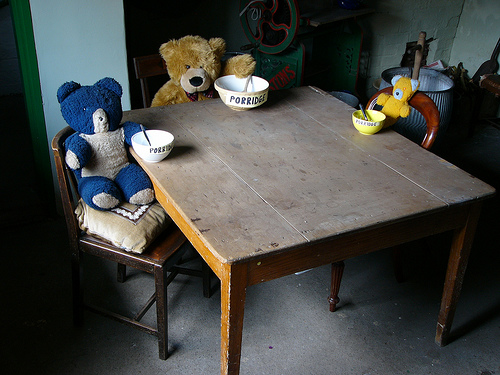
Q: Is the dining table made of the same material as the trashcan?
A: No, the dining table is made of wood and the trashcan is made of metal.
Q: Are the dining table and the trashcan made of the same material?
A: No, the dining table is made of wood and the trashcan is made of metal.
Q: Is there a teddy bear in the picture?
A: Yes, there is a teddy bear.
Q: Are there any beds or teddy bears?
A: Yes, there is a teddy bear.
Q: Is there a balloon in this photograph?
A: No, there are no balloons.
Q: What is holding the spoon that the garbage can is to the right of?
A: The teddy bear is holding the spoon.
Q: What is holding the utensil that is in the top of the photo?
A: The teddy bear is holding the spoon.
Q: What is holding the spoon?
A: The teddy bear is holding the spoon.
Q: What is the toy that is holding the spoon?
A: The toy is a teddy bear.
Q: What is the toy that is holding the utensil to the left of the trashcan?
A: The toy is a teddy bear.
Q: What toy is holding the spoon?
A: The toy is a teddy bear.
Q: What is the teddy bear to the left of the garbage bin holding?
A: The teddy bear is holding the spoon.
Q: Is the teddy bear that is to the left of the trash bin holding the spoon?
A: Yes, the teddy bear is holding the spoon.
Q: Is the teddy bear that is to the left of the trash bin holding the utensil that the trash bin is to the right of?
A: Yes, the teddy bear is holding the spoon.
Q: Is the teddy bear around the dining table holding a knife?
A: No, the teddy bear is holding the spoon.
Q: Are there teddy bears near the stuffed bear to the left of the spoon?
A: Yes, there is a teddy bear near the stuffed bear.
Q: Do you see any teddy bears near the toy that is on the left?
A: Yes, there is a teddy bear near the stuffed bear.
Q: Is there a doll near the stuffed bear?
A: No, there is a teddy bear near the stuffed bear.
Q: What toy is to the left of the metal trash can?
A: The toy is a teddy bear.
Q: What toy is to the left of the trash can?
A: The toy is a teddy bear.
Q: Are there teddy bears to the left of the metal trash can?
A: Yes, there is a teddy bear to the left of the trash bin.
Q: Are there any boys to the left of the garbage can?
A: No, there is a teddy bear to the left of the garbage can.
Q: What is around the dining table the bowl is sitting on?
A: The teddy bear is around the dining table.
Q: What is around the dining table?
A: The teddy bear is around the dining table.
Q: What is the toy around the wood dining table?
A: The toy is a teddy bear.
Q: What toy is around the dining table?
A: The toy is a teddy bear.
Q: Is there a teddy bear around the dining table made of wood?
A: Yes, there is a teddy bear around the dining table.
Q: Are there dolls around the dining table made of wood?
A: No, there is a teddy bear around the dining table.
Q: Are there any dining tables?
A: Yes, there is a dining table.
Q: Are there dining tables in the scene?
A: Yes, there is a dining table.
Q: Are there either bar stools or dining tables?
A: Yes, there is a dining table.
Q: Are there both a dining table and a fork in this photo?
A: No, there is a dining table but no forks.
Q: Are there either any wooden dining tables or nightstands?
A: Yes, there is a wood dining table.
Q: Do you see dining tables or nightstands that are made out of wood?
A: Yes, the dining table is made of wood.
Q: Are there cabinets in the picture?
A: No, there are no cabinets.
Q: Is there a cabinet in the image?
A: No, there are no cabinets.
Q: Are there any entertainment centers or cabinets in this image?
A: No, there are no cabinets or entertainment centers.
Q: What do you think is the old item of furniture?
A: The piece of furniture is a dining table.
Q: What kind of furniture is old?
A: The furniture is a dining table.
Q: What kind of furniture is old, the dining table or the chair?
A: The dining table is old.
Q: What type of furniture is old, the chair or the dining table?
A: The dining table is old.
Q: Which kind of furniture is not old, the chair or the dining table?
A: The chair is not old.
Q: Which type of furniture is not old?
A: The furniture is a chair.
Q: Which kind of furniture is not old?
A: The furniture is a chair.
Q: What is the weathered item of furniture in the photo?
A: The piece of furniture is a dining table.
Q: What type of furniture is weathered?
A: The furniture is a dining table.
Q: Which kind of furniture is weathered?
A: The furniture is a dining table.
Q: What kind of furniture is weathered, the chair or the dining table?
A: The dining table is weathered.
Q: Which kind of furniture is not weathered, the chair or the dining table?
A: The chair is not weathered.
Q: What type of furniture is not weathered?
A: The furniture is a chair.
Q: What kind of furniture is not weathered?
A: The furniture is a chair.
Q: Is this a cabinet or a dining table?
A: This is a dining table.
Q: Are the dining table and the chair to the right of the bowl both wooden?
A: Yes, both the dining table and the chair are wooden.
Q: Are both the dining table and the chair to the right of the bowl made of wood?
A: Yes, both the dining table and the chair are made of wood.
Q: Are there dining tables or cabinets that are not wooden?
A: No, there is a dining table but it is wooden.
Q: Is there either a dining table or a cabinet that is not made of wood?
A: No, there is a dining table but it is made of wood.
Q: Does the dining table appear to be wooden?
A: Yes, the dining table is wooden.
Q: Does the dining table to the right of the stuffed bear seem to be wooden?
A: Yes, the dining table is wooden.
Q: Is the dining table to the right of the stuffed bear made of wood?
A: Yes, the dining table is made of wood.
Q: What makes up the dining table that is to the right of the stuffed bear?
A: The dining table is made of wood.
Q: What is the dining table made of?
A: The dining table is made of wood.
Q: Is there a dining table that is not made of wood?
A: No, there is a dining table but it is made of wood.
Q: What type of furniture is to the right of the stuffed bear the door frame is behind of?
A: The piece of furniture is a dining table.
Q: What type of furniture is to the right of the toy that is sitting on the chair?
A: The piece of furniture is a dining table.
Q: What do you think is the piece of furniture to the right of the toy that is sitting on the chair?
A: The piece of furniture is a dining table.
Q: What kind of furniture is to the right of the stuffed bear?
A: The piece of furniture is a dining table.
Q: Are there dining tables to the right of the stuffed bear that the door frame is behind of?
A: Yes, there is a dining table to the right of the stuffed bear.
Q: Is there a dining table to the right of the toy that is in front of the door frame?
A: Yes, there is a dining table to the right of the stuffed bear.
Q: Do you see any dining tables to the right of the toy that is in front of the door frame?
A: Yes, there is a dining table to the right of the stuffed bear.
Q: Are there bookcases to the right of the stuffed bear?
A: No, there is a dining table to the right of the stuffed bear.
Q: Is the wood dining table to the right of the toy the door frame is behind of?
A: Yes, the dining table is to the right of the stuffed bear.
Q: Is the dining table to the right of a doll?
A: No, the dining table is to the right of the stuffed bear.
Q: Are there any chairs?
A: Yes, there is a chair.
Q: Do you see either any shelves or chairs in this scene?
A: Yes, there is a chair.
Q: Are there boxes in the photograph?
A: No, there are no boxes.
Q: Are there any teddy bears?
A: Yes, there is a teddy bear.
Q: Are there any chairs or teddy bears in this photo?
A: Yes, there is a teddy bear.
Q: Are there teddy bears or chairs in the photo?
A: Yes, there is a teddy bear.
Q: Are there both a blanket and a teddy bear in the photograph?
A: No, there is a teddy bear but no blankets.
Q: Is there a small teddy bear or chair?
A: Yes, there is a small teddy bear.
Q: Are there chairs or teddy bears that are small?
A: Yes, the teddy bear is small.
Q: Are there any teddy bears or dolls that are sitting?
A: Yes, the teddy bear is sitting.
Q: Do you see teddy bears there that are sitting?
A: Yes, there is a teddy bear that is sitting.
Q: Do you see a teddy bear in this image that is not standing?
A: Yes, there is a teddy bear that is sitting .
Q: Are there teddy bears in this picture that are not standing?
A: Yes, there is a teddy bear that is sitting.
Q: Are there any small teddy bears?
A: Yes, there is a small teddy bear.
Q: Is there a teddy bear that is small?
A: Yes, there is a teddy bear that is small.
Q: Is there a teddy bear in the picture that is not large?
A: Yes, there is a small teddy bear.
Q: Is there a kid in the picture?
A: No, there are no children.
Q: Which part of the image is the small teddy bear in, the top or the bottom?
A: The teddy bear is in the top of the image.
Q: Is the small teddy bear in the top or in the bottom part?
A: The teddy bear is in the top of the image.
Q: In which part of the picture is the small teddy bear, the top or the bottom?
A: The teddy bear is in the top of the image.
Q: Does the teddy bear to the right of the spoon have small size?
A: Yes, the teddy bear is small.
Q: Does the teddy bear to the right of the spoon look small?
A: Yes, the teddy bear is small.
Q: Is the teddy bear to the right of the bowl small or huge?
A: The teddy bear is small.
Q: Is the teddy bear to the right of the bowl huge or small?
A: The teddy bear is small.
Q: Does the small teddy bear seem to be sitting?
A: Yes, the teddy bear is sitting.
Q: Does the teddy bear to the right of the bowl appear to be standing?
A: No, the teddy bear is sitting.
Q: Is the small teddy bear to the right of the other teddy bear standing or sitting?
A: The teddy bear is sitting.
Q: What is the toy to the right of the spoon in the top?
A: The toy is a teddy bear.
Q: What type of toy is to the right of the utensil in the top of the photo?
A: The toy is a teddy bear.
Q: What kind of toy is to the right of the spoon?
A: The toy is a teddy bear.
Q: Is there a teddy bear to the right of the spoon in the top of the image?
A: Yes, there is a teddy bear to the right of the spoon.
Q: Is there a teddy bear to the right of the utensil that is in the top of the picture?
A: Yes, there is a teddy bear to the right of the spoon.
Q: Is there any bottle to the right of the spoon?
A: No, there is a teddy bear to the right of the spoon.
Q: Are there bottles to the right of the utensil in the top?
A: No, there is a teddy bear to the right of the spoon.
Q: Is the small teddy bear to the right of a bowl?
A: Yes, the teddy bear is to the right of a bowl.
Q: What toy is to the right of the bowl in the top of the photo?
A: The toy is a teddy bear.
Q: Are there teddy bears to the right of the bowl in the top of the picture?
A: Yes, there is a teddy bear to the right of the bowl.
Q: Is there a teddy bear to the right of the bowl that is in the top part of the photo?
A: Yes, there is a teddy bear to the right of the bowl.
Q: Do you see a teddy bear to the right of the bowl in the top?
A: Yes, there is a teddy bear to the right of the bowl.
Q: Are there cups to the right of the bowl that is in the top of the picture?
A: No, there is a teddy bear to the right of the bowl.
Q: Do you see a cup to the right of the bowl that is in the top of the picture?
A: No, there is a teddy bear to the right of the bowl.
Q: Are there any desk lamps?
A: No, there are no desk lamps.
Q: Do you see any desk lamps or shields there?
A: No, there are no desk lamps or shields.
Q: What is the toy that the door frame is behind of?
A: The toy is a stuffed bear.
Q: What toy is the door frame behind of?
A: The door frame is behind the stuffed bear.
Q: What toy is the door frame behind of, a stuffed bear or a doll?
A: The door frame is behind a stuffed bear.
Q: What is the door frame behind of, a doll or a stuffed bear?
A: The door frame is behind a stuffed bear.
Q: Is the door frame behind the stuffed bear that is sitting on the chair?
A: Yes, the door frame is behind the stuffed bear.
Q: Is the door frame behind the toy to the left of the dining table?
A: Yes, the door frame is behind the stuffed bear.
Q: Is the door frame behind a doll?
A: No, the door frame is behind the stuffed bear.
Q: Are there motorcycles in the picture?
A: No, there are no motorcycles.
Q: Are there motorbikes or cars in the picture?
A: No, there are no motorbikes or cars.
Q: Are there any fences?
A: No, there are no fences.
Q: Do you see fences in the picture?
A: No, there are no fences.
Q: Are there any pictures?
A: No, there are no pictures.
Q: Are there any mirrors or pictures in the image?
A: No, there are no pictures or mirrors.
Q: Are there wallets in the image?
A: No, there are no wallets.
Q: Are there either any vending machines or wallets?
A: No, there are no wallets or vending machines.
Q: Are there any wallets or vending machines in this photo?
A: No, there are no wallets or vending machines.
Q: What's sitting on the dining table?
A: The bowl is sitting on the dining table.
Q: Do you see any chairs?
A: Yes, there is a chair.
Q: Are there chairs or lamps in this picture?
A: Yes, there is a chair.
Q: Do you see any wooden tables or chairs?
A: Yes, there is a wood chair.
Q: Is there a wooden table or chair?
A: Yes, there is a wood chair.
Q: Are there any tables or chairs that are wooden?
A: Yes, the chair is wooden.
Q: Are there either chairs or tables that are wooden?
A: Yes, the chair is wooden.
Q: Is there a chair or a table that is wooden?
A: Yes, the chair is wooden.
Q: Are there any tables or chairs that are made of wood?
A: Yes, the chair is made of wood.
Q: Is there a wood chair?
A: Yes, there is a chair that is made of wood.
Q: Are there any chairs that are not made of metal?
A: Yes, there is a chair that is made of wood.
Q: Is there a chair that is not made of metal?
A: Yes, there is a chair that is made of wood.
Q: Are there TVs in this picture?
A: No, there are no tvs.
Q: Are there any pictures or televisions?
A: No, there are no televisions or pictures.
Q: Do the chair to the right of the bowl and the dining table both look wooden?
A: Yes, both the chair and the dining table are wooden.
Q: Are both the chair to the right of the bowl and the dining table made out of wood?
A: Yes, both the chair and the dining table are made of wood.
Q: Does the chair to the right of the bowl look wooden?
A: Yes, the chair is wooden.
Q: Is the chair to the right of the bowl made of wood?
A: Yes, the chair is made of wood.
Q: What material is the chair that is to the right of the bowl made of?
A: The chair is made of wood.